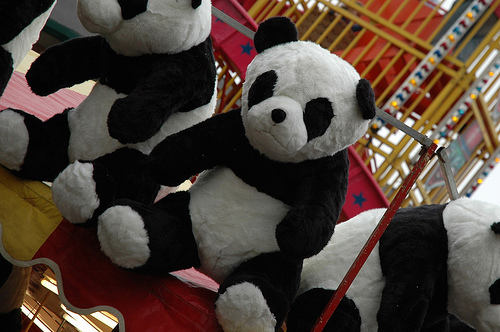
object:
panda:
[0, 0, 220, 233]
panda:
[89, 15, 377, 332]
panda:
[282, 193, 500, 332]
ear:
[250, 14, 301, 56]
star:
[350, 191, 370, 209]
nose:
[269, 107, 289, 125]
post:
[304, 139, 438, 332]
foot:
[90, 196, 165, 276]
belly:
[187, 157, 298, 278]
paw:
[274, 219, 334, 261]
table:
[0, 48, 286, 331]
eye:
[301, 95, 336, 145]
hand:
[145, 143, 194, 189]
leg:
[96, 189, 200, 275]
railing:
[211, 0, 500, 209]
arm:
[273, 147, 352, 261]